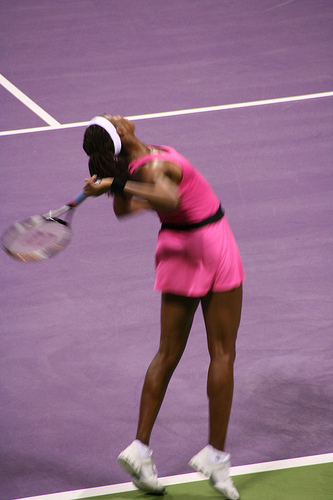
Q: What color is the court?
A: Purple.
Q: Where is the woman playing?
A: Tennis court.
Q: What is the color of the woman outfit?
A: Pink.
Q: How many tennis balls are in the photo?
A: Zero.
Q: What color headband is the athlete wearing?
A: White.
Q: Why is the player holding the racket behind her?
A: To swing at the ball.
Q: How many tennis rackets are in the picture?
A: One.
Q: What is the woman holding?
A: Tennis racket.